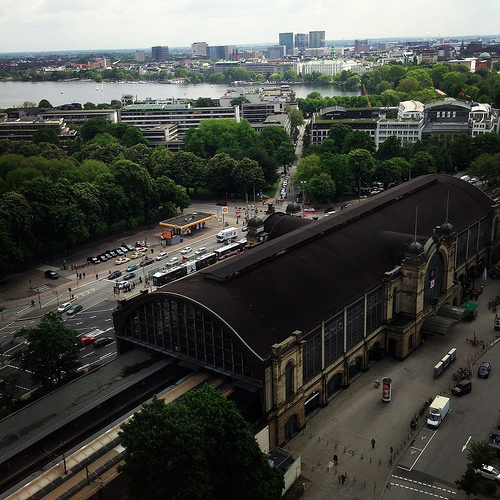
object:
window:
[194, 351, 206, 366]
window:
[132, 315, 141, 325]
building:
[109, 172, 500, 452]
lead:
[133, 167, 135, 170]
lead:
[97, 190, 117, 200]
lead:
[100, 173, 106, 183]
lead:
[220, 162, 222, 165]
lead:
[243, 171, 246, 175]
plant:
[202, 151, 243, 199]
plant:
[231, 156, 266, 197]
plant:
[103, 156, 151, 228]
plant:
[0, 190, 45, 263]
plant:
[106, 157, 157, 228]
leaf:
[109, 125, 122, 134]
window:
[183, 304, 194, 318]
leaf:
[80, 159, 98, 171]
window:
[154, 337, 166, 350]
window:
[183, 320, 195, 330]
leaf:
[76, 187, 92, 196]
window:
[204, 352, 216, 367]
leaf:
[132, 167, 151, 183]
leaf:
[123, 133, 136, 146]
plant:
[70, 114, 155, 148]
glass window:
[176, 326, 190, 339]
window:
[363, 282, 388, 342]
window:
[344, 296, 366, 356]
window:
[299, 323, 327, 389]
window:
[452, 228, 473, 274]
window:
[475, 219, 490, 256]